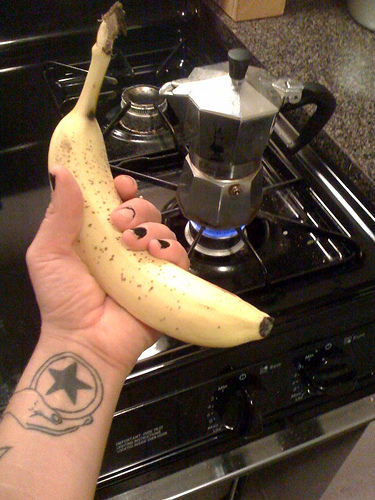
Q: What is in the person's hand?
A: A banana.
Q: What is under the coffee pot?
A: A flame.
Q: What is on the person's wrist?
A: A tattoo.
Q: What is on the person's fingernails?
A: Nail polish.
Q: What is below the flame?
A: Knobs.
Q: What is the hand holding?
A: A banana.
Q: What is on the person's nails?
A: Black polish.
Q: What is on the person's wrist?
A: A tattoo.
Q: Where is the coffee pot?
A: On the stove.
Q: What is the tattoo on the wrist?
A: A hand holding a ball with a star in it.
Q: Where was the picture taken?
A: In a kitchen.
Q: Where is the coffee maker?
A: On the stove top.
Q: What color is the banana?
A: Yellow.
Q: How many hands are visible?
A: Two.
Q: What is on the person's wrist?
A: A tattoo.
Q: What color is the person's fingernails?
A: Black.